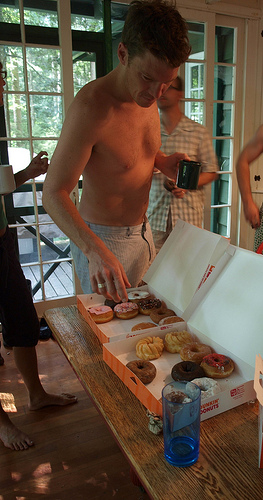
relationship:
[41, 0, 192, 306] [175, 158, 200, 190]
man holding cup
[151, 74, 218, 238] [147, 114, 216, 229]
man wearing shirt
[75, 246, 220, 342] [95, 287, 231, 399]
two boxes of donuts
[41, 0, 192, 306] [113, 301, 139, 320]
man selecting a donut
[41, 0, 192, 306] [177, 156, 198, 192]
man holding coffee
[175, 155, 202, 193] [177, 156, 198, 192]
cup of coffee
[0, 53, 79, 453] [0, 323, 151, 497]
man standing on a floor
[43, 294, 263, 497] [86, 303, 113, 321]
table on it donuts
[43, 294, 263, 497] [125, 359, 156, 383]
table on it donuts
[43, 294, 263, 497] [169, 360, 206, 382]
table on it donuts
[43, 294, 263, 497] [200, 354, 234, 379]
table on it donuts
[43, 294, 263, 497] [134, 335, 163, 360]
table on it donuts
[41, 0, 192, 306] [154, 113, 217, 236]
man not wearing shirt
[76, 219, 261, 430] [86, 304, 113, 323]
boxes of donut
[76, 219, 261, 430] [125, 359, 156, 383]
boxes of donuts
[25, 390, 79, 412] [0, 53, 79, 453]
bare foot of a man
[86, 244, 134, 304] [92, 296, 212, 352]
hand reaching for a doughnut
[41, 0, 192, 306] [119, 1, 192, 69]
man with hair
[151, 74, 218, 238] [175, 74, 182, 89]
man with hair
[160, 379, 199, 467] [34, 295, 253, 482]
glass on table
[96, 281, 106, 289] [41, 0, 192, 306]
ring on man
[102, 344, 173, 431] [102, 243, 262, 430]
front of doughnuts`s box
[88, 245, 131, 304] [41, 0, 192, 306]
hand on man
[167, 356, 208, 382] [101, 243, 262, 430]
dunkin donut in carton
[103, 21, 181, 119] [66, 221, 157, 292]
man wears pants